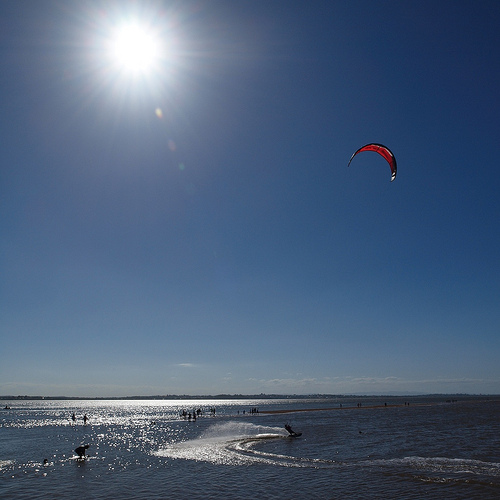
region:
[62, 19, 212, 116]
sun in the sky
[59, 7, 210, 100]
bright sun in the sky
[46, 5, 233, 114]
the sun is shining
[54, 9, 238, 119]
sun is shining bright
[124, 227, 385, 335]
patch of blue sky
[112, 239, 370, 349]
patch of clear blue sky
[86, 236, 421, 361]
blue sky on clear day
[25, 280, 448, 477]
beautiful beach scene during day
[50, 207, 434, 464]
lovely view of the beach sky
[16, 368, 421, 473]
people outside in beach water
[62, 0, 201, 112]
bright sun in blue sky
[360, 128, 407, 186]
red kite in blue sky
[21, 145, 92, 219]
white clouds in blue sky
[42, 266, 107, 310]
white clouds in blue sky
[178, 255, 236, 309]
white clouds in blue sky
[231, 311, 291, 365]
white clouds in blue sky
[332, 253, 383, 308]
white clouds in blue sky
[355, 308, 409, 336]
white clouds in blue sky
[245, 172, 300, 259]
white clouds in blue sky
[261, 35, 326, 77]
white clouds in blue sky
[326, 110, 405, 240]
a red kite in the sky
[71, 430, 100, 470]
a person in the water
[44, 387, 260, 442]
several people in the water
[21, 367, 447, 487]
a large body of water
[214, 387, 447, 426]
a sand barge in the water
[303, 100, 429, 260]
a kite flying in the sky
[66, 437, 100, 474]
a person bent over in the water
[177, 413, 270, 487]
waves in the water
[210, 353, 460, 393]
white clouds in a blue sky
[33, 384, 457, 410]
land next to the water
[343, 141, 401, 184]
red kite in the blue sky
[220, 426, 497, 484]
path in water of the water skier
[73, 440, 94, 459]
person leaning over the water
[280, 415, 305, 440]
person riding on board holding kite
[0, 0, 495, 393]
cloudless blue sky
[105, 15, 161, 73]
the sun in the sky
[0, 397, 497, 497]
dark blue water with people in it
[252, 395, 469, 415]
strip of brown land in the water with people standing on it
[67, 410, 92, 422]
two people standing in the water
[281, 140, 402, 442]
people parasailing in the water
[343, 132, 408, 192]
red parasail in the sky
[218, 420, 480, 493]
wake from a parasailer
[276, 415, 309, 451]
man on his surfboard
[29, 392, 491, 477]
many people in shallow water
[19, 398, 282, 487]
sunlight glinting off of the water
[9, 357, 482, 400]
clouds gathering along the horizon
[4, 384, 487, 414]
land across the water on the horizon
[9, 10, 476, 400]
mostly sunny blue skies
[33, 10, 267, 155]
sunrays captured by the camera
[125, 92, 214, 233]
flare caused by the reflection on the camera lens